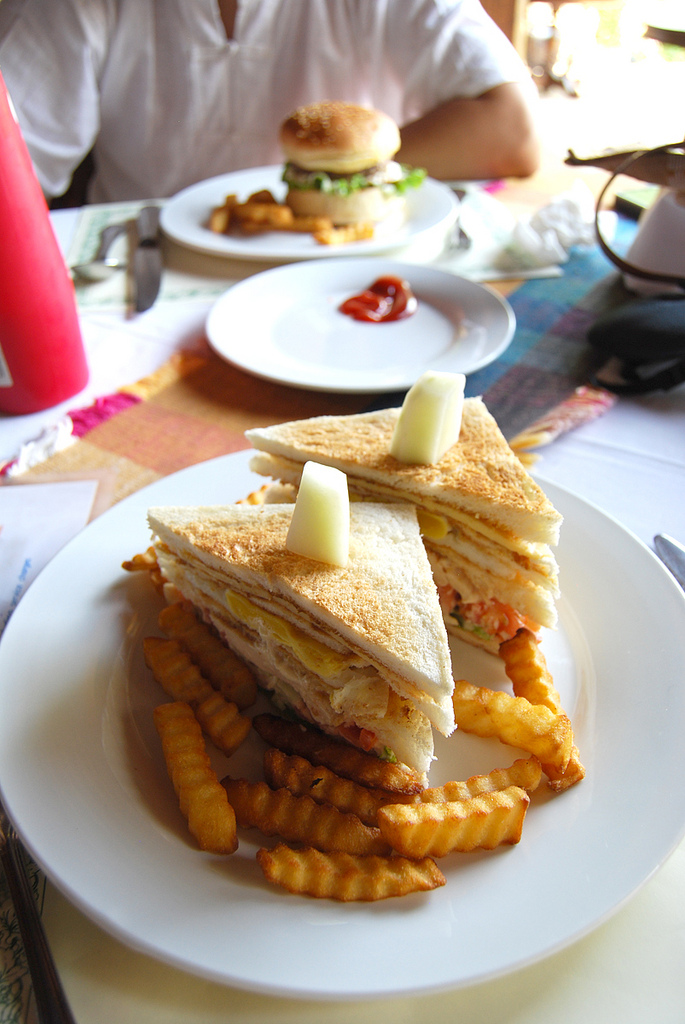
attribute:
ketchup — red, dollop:
[353, 275, 406, 324]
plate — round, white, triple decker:
[265, 324, 461, 372]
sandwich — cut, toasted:
[210, 407, 464, 707]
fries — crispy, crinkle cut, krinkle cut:
[264, 773, 460, 852]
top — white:
[55, 14, 173, 118]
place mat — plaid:
[185, 262, 227, 301]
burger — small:
[258, 108, 383, 220]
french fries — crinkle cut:
[210, 184, 293, 225]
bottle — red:
[6, 269, 92, 408]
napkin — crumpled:
[478, 212, 531, 277]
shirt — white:
[29, 73, 151, 160]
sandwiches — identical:
[355, 491, 514, 584]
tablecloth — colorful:
[526, 303, 564, 382]